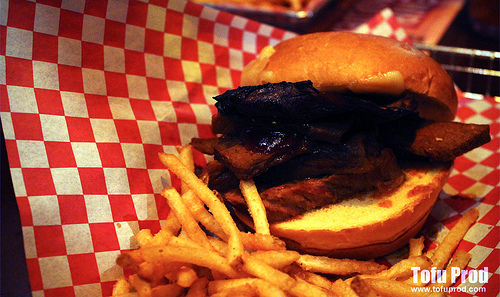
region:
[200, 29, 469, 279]
burger on the paper wrapper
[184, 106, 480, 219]
meat in the bun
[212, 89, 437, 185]
meat in the bun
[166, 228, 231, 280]
golden fries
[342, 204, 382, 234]
the bun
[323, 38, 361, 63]
top of the bun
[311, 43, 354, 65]
the bun is brown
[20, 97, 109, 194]
checkered paper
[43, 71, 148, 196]
the paper is red and white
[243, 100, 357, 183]
meat on the burger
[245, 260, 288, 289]
the fries are brown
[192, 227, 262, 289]
fries are golden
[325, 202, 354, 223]
inside of the bun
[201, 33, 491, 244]
a small brisket sandwich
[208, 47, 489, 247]
smoked meat on a sandwich bun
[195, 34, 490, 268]
barbeque meat in a bun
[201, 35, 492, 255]
meat sandwich with no condiments